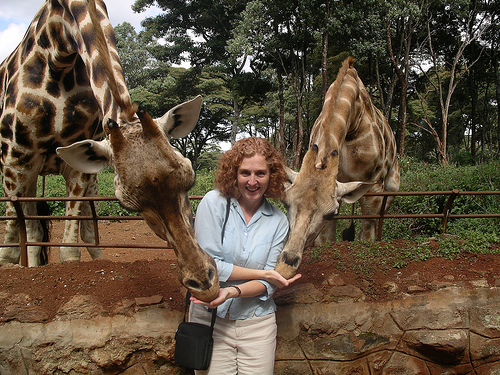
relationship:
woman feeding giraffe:
[192, 136, 303, 375] [4, 17, 239, 356]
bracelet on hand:
[227, 279, 255, 301] [177, 268, 260, 327]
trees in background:
[114, 1, 498, 167] [104, 8, 426, 84]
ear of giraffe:
[338, 180, 376, 205] [274, 58, 400, 279]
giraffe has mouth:
[241, 65, 428, 320] [275, 255, 298, 278]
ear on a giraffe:
[337, 181, 377, 203] [274, 58, 400, 279]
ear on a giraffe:
[278, 154, 295, 190] [274, 58, 400, 279]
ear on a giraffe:
[52, 134, 117, 179] [1, 0, 220, 305]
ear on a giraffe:
[146, 90, 210, 142] [1, 0, 220, 305]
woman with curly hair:
[192, 136, 303, 375] [216, 137, 288, 200]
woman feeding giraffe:
[192, 136, 303, 375] [1, 0, 220, 305]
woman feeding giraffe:
[192, 136, 303, 375] [267, 59, 402, 309]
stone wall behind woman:
[0, 282, 498, 373] [192, 136, 303, 375]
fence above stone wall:
[1, 188, 498, 265] [0, 282, 498, 373]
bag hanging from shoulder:
[174, 290, 216, 371] [185, 183, 233, 220]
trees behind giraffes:
[105, 7, 205, 189] [3, 2, 221, 294]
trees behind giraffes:
[189, 2, 282, 175] [3, 2, 221, 294]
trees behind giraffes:
[290, 7, 382, 186] [3, 2, 221, 294]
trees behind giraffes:
[377, 2, 451, 189] [274, 48, 404, 280]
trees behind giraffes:
[423, 2, 495, 172] [274, 48, 404, 280]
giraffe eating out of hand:
[274, 58, 400, 279] [263, 250, 303, 290]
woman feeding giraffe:
[201, 141, 291, 372] [1, 0, 220, 305]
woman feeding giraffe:
[201, 141, 291, 372] [274, 58, 400, 279]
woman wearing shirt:
[192, 136, 303, 375] [189, 196, 321, 309]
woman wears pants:
[192, 136, 303, 375] [178, 297, 278, 373]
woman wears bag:
[192, 136, 303, 375] [172, 286, 219, 373]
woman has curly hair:
[192, 136, 303, 375] [221, 138, 288, 199]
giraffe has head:
[0, 0, 218, 302] [107, 98, 201, 270]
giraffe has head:
[274, 58, 400, 279] [288, 60, 326, 268]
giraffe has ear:
[1, 0, 220, 305] [156, 92, 203, 139]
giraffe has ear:
[1, 0, 220, 305] [51, 136, 111, 173]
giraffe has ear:
[274, 58, 400, 279] [336, 180, 381, 205]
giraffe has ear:
[274, 58, 400, 279] [278, 161, 297, 191]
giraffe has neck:
[1, 0, 220, 305] [62, 2, 149, 127]